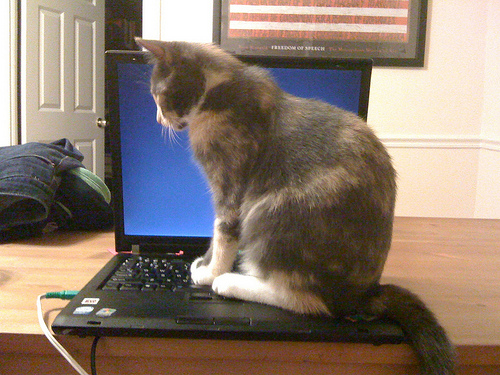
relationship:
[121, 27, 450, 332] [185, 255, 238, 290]
cat has paws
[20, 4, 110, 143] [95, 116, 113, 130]
door has knob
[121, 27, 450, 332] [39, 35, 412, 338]
cat on laptop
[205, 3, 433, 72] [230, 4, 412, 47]
poster of flag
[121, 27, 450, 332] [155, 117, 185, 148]
cat has whiskers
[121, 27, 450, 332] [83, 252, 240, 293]
cat on keyboard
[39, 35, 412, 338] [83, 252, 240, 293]
laptop has keyboard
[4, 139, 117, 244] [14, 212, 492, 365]
clothing on desk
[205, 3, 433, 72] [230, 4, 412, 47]
picture of flag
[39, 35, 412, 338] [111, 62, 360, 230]
desktop has screen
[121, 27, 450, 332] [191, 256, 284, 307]
cat has feet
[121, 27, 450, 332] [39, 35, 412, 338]
cat on computer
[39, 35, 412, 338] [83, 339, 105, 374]
computer has wire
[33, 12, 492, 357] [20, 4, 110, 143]
room has door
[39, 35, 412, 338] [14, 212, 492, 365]
computer on table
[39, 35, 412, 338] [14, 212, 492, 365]
laptop on table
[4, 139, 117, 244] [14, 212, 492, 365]
clothes on table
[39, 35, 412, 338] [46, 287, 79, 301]
laptop has cord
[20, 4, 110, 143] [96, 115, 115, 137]
door has doorknob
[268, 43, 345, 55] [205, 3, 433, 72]
words on picture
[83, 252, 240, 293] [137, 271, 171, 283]
keys has keys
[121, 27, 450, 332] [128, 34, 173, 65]
cat has ear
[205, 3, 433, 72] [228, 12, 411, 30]
poster has stripe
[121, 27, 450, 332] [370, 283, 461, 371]
cat has tail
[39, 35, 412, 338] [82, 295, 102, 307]
computer has sticker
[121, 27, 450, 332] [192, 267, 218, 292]
cat has paw